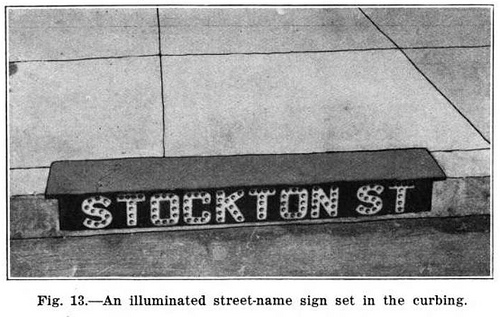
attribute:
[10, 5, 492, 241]
sidewalk — ground, big, gray, squares, empty, concrete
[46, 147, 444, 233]
plate — black, white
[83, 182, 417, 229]
word — stockton st, illuminated, street name, street sign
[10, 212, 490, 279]
road — black, pavement, clear, asphalt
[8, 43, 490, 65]
line — black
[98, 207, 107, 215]
dot — lightbulb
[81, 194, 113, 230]
letter s — illuminated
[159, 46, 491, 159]
square — concrete